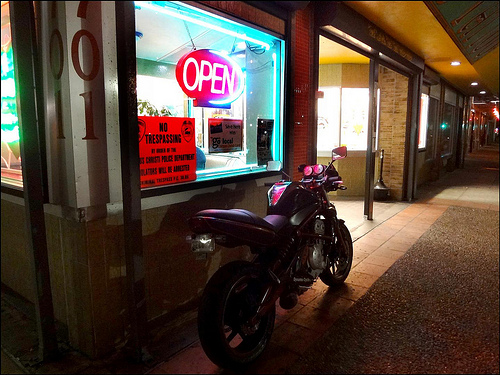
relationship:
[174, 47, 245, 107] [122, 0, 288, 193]
sign in window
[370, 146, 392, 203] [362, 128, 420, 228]
ash container by wall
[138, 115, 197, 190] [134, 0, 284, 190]
sign hanging in window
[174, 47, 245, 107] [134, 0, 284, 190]
sign hanging in window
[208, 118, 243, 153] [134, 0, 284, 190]
sign hanging in window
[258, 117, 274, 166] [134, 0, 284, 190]
sign hanging in window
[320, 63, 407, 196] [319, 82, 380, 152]
brick work surrounding window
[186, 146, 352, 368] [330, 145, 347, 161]
motorcycle has side mirror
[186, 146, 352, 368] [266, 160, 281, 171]
motorcycle has side mirror